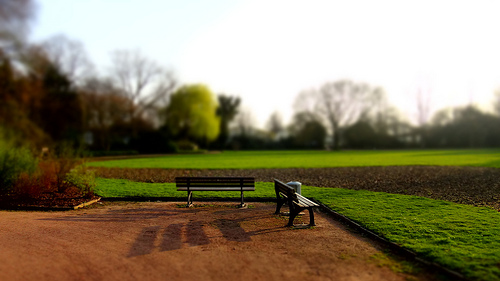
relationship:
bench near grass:
[272, 177, 319, 226] [70, 152, 495, 279]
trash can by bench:
[288, 180, 300, 201] [266, 174, 326, 232]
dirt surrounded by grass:
[87, 163, 496, 209] [354, 196, 468, 241]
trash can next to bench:
[288, 180, 300, 201] [272, 177, 319, 226]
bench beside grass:
[272, 177, 319, 226] [354, 196, 468, 241]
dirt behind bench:
[87, 163, 496, 209] [163, 172, 266, 206]